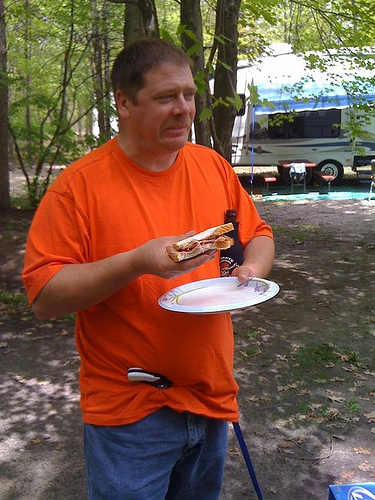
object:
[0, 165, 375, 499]
ground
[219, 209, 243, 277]
beer container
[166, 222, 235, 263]
sandwich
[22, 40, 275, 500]
man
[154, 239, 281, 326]
plate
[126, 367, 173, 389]
pistol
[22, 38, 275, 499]
man is eating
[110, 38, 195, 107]
brown hair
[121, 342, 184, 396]
white item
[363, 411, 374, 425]
ground is brown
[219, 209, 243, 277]
blue beer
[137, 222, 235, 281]
holding sandwich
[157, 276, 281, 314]
plate is circular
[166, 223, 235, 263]
bread sandwich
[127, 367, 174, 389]
white handle grip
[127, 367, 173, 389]
pistol in waistband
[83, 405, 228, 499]
blue denim pants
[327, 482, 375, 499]
bud light box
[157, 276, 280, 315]
paper plate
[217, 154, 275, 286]
crook of arm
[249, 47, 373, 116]
blue roll out awning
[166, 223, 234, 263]
sandwich in man's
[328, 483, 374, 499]
beer on ground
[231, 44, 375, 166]
camper in the woods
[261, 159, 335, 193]
picnic table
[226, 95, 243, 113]
green leaves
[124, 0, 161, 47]
trunks of a tree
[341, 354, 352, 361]
brown leaves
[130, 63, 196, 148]
face of a man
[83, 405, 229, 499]
man's blue jean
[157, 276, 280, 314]
white paper plate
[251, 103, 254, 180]
part of a blue stick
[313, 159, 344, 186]
"the tire of a motor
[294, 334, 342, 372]
small patch of grass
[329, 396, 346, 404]
brown leaf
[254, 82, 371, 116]
blue canopy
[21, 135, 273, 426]
man's orange t-shirt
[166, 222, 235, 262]
sandwich half eaten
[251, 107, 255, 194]
pole in the ground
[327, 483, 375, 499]
case of beer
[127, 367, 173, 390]
gun in a man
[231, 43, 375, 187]
trailer in a field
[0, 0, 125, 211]
tree in a field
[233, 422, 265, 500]
an object